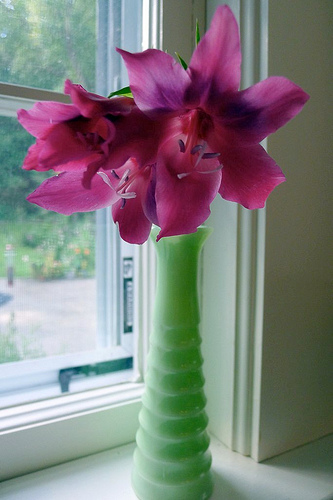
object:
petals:
[61, 70, 133, 119]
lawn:
[3, 217, 95, 276]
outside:
[4, 0, 101, 357]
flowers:
[71, 241, 89, 277]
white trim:
[138, 1, 207, 65]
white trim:
[1, 384, 146, 481]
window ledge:
[2, 421, 330, 499]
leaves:
[173, 49, 187, 70]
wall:
[192, 0, 331, 468]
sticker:
[123, 257, 134, 335]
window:
[0, 0, 203, 479]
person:
[4, 242, 16, 287]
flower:
[115, 4, 309, 244]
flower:
[18, 80, 142, 193]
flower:
[27, 140, 164, 246]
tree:
[0, 0, 97, 275]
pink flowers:
[18, 2, 310, 243]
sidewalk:
[0, 275, 106, 356]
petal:
[200, 77, 309, 146]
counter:
[0, 430, 333, 500]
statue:
[0, 265, 19, 310]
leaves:
[106, 86, 135, 100]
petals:
[110, 41, 188, 115]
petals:
[184, 2, 242, 121]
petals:
[211, 133, 286, 214]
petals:
[157, 129, 221, 251]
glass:
[129, 225, 212, 500]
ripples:
[130, 316, 215, 500]